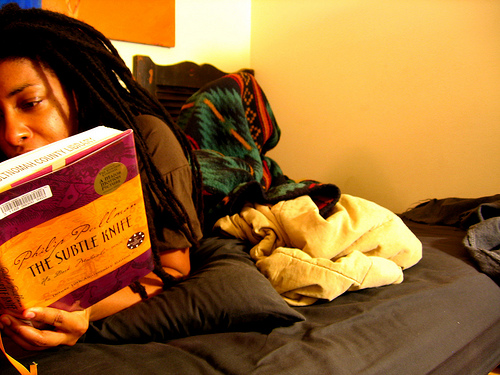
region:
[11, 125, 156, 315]
Library book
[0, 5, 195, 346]
girl reading a book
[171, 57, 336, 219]
fuzzy blanket with geometric printed pattern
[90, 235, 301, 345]
black pillow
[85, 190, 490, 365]
large unmade bed with black sheets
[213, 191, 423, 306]
wadded-up white blanket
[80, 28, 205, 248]
dreadlocks hair style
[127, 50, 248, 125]
black swinging saloon door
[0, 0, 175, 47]
orange and blue hanging painting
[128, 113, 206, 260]
girl is wearing a brown t-shirt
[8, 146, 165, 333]
A book called "The Subtle Knife"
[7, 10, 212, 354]
a woman reading a book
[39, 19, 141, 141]
dread-locks in the woman's hair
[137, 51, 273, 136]
a chair in the background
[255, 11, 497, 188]
a white wall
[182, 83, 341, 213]
A patterned decorative jacket.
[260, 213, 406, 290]
a white comforter.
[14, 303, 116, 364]
the woman's hand holding a book.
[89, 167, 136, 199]
a sticker on the book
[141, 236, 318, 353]
a black pillow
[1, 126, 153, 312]
paper cover on book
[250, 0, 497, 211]
wall painted pale yellow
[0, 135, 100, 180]
black writing on edge of book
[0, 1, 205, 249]
long braided black hair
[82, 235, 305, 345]
pillow in dark brown pillowcase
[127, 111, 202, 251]
man wearing brown shirt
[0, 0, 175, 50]
blue and orange wall hanging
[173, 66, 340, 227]
blanket is green, orange, black and red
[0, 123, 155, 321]
book is open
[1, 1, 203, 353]
man is reading 'The Subtle Knife' book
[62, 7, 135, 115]
portion of woman's black dreads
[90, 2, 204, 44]
portion of orange picture with round brown dot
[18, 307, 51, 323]
tip of woman's fingers with pink manicured nails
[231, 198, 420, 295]
crumpled white garment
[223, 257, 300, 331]
portion of brown felt pillow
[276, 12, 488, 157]
solid light yellow wall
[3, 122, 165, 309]
large book with yellow and purple cover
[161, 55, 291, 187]
large green and orange silk garment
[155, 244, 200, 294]
portion of woman's arm resting on pillow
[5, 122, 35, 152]
woman's protruding nose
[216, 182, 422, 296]
A wadded up white blanket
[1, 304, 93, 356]
Fingers holding up a book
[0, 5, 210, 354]
A person reading a book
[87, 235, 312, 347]
A dark pillow a person is laying on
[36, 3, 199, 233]
Dread locks on this persons head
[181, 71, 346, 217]
A colorful blanket laying on the bed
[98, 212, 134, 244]
The word KNIFE written on the front of the book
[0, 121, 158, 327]
A purple and yellow book titled "The Subtle Knife"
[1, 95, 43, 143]
A nose on the face of the person reading a book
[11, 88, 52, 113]
Eyeball of the person reading the book